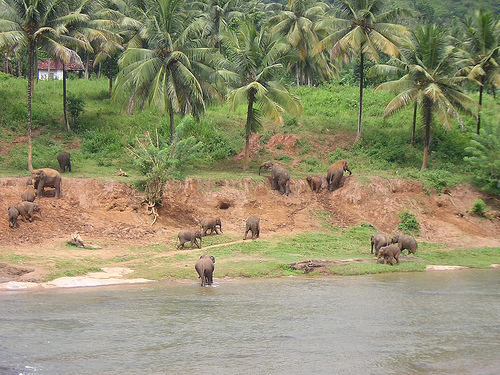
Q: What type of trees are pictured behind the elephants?
A: Palm trees.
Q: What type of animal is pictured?
A: Elephant.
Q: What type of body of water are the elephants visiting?
A: River.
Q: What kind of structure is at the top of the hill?
A: House.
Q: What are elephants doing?
A: Drinking.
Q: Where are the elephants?
A: Tropics.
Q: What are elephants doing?
A: Walking.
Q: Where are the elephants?
A: Banks.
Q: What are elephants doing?
A: Climbing.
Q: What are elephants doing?
A: Teaching young.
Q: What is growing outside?
A: Shrub.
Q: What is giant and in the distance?
A: A palm tree.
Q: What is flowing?
A: A lake.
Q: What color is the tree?
A: Green.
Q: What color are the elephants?
A: Brown.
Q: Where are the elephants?
A: By the waters edge.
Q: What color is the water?
A: Gray.